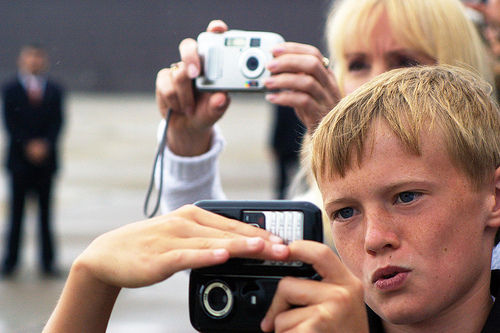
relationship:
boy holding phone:
[62, 69, 496, 331] [189, 198, 325, 331]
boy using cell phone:
[62, 69, 496, 331] [189, 198, 325, 331]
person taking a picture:
[62, 69, 496, 331] [194, 198, 331, 332]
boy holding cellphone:
[62, 69, 496, 331] [189, 198, 325, 331]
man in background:
[4, 47, 80, 278] [3, 2, 500, 275]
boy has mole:
[62, 69, 496, 331] [388, 253, 396, 260]